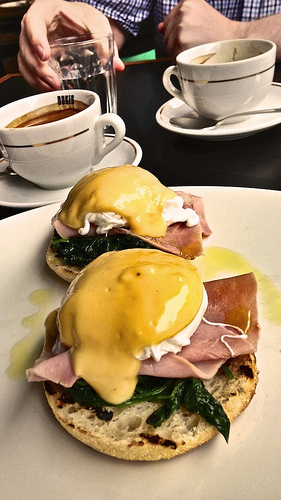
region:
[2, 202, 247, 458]
food on the plate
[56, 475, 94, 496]
the plate is glass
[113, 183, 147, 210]
cheese on the burger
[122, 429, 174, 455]
burnt part of bun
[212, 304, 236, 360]
meat on the burger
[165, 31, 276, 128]
teacup on the plate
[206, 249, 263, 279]
sauce on the plate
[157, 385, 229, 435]
leaf on the burger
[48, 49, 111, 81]
liquid in the glass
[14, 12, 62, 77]
fingers on the hand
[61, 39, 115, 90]
a glass on the table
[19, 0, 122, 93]
the hand of a person holding a glass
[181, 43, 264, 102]
a cup on a saucer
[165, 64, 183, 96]
the handle of a cup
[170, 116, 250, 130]
a spoon on the saucer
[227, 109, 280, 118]
the handle of a spoon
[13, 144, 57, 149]
a stripe on a cup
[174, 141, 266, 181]
a black table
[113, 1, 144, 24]
a person wearing a checked shirt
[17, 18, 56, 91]
the fingers of a hand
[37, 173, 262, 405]
food on the plate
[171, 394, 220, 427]
leaf on the bun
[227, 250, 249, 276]
sauce on the plate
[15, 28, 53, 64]
fingers on the hand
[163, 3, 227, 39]
hand of hte person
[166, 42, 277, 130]
a coffee mug on the table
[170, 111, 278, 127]
a spoon on a plate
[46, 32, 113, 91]
a water glass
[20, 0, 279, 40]
a man in a checkered shirt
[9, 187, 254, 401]
a plate of food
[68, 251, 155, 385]
cheese on top of the food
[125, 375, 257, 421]
spinach on the bread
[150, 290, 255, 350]
ham on the food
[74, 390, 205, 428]
the bread on the bottom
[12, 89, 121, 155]
a full coffee mug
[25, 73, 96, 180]
white cup on saucer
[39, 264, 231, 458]
muffin with white egg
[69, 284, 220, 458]
yellow hollandaise on egg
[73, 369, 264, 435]
green vegetable on muffin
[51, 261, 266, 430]
pink ham on muffin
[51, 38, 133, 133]
white and clear glass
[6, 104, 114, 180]
coffee in white cup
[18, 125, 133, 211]
saucer on black table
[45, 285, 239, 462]
brown muffin is toasted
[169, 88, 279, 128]
spoon on white saucer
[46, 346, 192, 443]
this is eggs benedict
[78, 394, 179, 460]
the bread is toasted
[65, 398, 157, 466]
the bread is black and tan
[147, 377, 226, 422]
this is spinach leaf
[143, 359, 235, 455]
the spinach is green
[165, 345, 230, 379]
this is a slice of ham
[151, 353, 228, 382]
the ham slice is pink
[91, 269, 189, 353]
the egg is under the sauce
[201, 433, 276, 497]
the plate is white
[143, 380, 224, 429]
the spinach is green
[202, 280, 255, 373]
the meat is ham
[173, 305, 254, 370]
egg is on top of ham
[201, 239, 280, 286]
oil is on the plate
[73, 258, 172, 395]
the sauce is yellow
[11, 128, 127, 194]
cup is on the saucer